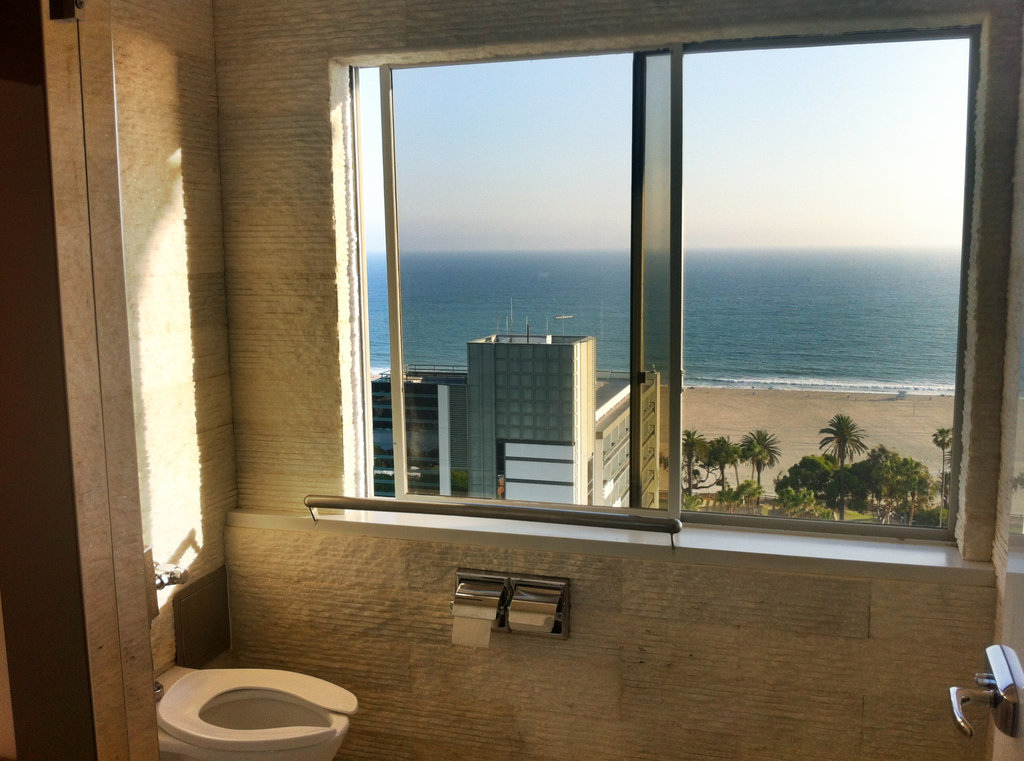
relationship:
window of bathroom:
[342, 32, 973, 549] [7, 2, 1021, 754]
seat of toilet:
[154, 662, 358, 747] [154, 666, 356, 757]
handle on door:
[943, 677, 993, 732] [986, 458, 1021, 757]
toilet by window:
[163, 659, 343, 755] [360, 78, 957, 554]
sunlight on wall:
[135, 236, 203, 569] [42, 1, 257, 647]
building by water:
[414, 337, 616, 493] [477, 242, 1022, 493]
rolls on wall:
[447, 589, 553, 646] [220, 2, 998, 757]